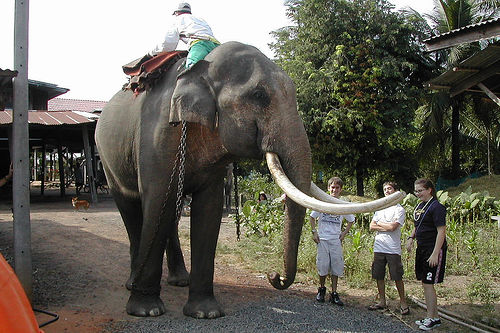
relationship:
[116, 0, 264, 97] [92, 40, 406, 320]
man on elephant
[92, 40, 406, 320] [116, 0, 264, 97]
elephant under man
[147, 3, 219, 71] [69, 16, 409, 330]
man under elephant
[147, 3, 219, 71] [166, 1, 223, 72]
man wearing pants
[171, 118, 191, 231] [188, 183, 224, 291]
chain on leg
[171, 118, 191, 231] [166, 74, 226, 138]
chain on ears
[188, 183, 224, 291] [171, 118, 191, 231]
leg with chain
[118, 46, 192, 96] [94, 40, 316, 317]
blanket on elephant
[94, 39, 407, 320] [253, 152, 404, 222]
elephant has tusks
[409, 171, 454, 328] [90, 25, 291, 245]
girl smiles at elephant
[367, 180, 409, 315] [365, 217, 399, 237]
boy with arms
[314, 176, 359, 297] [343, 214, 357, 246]
boy with arm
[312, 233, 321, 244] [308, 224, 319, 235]
hand with watch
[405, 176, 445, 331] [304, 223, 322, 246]
girl with hand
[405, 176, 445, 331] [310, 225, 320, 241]
girl with watch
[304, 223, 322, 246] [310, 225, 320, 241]
hand with watch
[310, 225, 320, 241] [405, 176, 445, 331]
watch on girl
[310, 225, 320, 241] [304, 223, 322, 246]
watch on hand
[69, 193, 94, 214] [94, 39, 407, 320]
dog behind elephant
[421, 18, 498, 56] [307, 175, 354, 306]
roof behind kid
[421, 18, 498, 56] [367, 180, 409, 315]
roof behind boy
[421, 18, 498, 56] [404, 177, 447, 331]
roof behind kid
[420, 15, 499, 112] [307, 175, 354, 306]
building behind kid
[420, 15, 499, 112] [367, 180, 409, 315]
building behind boy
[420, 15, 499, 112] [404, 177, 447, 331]
building behind kid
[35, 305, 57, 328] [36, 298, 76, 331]
black cord on ground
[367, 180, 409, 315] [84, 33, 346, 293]
boy watching elephant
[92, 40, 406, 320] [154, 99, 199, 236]
elephant wearing chain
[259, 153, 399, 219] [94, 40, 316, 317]
tusk on elephant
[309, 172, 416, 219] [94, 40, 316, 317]
tusk on elephant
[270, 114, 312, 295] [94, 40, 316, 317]
trunk on elephant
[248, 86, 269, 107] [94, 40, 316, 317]
eye on elephant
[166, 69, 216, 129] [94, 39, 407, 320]
ear on elephant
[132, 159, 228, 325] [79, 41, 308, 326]
leg on elephant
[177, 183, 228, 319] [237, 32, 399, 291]
leg on elephant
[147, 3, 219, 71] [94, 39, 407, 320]
man sitting on top of elephant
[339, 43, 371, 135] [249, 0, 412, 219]
leaves on tree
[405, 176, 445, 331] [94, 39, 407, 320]
girl standing by an elephant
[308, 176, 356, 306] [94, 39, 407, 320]
boy looking at elephant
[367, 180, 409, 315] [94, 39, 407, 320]
boy looking at elephant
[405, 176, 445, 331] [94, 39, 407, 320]
girl looking at elephant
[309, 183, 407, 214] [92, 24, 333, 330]
tusk on elephant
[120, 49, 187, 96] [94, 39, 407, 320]
blanket on elephant